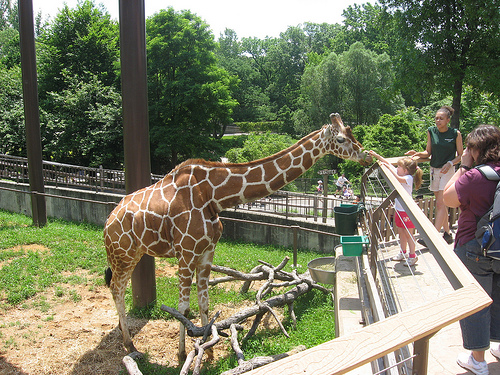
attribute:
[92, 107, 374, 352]
giraffe — large, being exhibited, in a den, brown yellow white, white, yellow brown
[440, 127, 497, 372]
person — taking a photograph, snapping photo, taking a picture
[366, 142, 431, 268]
girl — kid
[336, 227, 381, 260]
baskets — green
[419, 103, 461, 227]
woman — zoo employee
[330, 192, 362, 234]
trash cans — green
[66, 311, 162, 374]
dirt — not grass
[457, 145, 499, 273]
lady — taking a picture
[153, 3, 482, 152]
trees — green, in the back, a variety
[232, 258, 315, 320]
branch — light brown